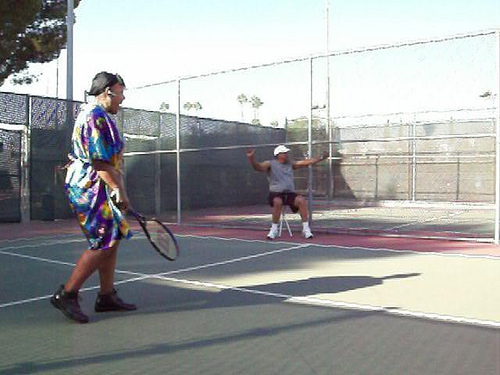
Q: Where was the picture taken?
A: At a tennis court.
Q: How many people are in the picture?
A: Two.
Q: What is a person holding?
A: A tennis racket.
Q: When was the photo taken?
A: Daytime.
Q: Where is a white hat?
A: On man's head.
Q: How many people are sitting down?
A: One.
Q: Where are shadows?
A: On the tennis court.